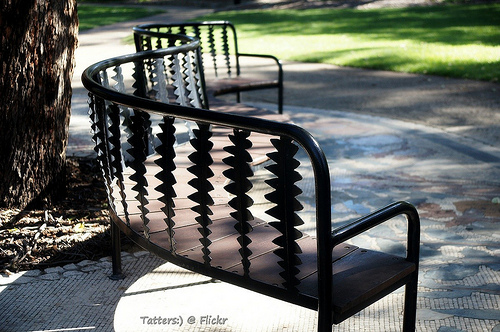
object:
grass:
[126, 0, 498, 81]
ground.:
[346, 87, 499, 329]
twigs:
[17, 201, 51, 263]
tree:
[0, 0, 79, 210]